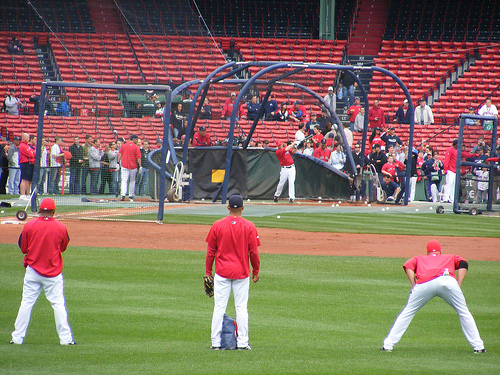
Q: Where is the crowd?
A: Behind the fence.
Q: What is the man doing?
A: Waiting for practice.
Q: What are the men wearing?
A: Uniform.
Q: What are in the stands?
A: Bleachers.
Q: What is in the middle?
A: Dirt.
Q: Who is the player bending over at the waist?
A: The right player.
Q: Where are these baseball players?
A: On baseball field.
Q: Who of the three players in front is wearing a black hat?
A: Middle player.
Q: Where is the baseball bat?
A: In the hands.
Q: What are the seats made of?
A: Plastic.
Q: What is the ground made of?
A: Grass and dirt.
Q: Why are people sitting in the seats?
A: To watch.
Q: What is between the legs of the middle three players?
A: A blue bag.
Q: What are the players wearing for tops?
A: Red jersey.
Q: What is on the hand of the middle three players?
A: A baseball mitt.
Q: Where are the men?
A: On the baseball field.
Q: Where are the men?
A: Baseball field.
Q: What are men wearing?
A: A hat.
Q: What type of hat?
A: Baseball.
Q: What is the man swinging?
A: Bat.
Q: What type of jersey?
A: Baseball.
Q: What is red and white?
A: Jersey.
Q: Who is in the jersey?
A: A man.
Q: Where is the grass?
A: On field.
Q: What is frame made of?
A: Metal.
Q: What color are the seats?
A: Red.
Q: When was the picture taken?
A: Daytime.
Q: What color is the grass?
A: Green.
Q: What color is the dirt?
A: Brown.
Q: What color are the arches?
A: Blue.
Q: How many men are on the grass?
A: Three.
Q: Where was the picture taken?
A: At a baseball park.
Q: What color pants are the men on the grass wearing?
A: White.